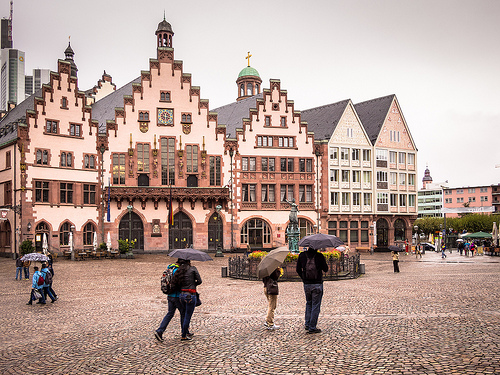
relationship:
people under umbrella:
[147, 248, 335, 350] [168, 247, 208, 265]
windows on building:
[67, 191, 73, 204] [209, 76, 325, 247]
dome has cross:
[236, 65, 260, 78] [243, 50, 253, 64]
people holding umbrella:
[294, 247, 328, 332] [254, 242, 291, 282]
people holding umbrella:
[294, 247, 328, 332] [166, 242, 212, 264]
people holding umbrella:
[294, 247, 328, 332] [298, 232, 337, 253]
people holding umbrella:
[294, 247, 328, 332] [298, 231, 343, 245]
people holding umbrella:
[294, 247, 328, 332] [387, 239, 405, 252]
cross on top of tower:
[243, 48, 254, 66] [238, 64, 260, 97]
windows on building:
[249, 127, 309, 153] [5, 5, 430, 255]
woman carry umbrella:
[260, 266, 283, 331] [255, 244, 290, 280]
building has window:
[0, 6, 331, 263] [132, 107, 152, 125]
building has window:
[0, 6, 331, 263] [174, 107, 195, 127]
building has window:
[0, 6, 331, 263] [133, 166, 153, 186]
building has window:
[0, 6, 331, 263] [179, 167, 201, 187]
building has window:
[0, 6, 331, 263] [258, 156, 280, 176]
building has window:
[0, 8, 418, 261] [241, 183, 258, 204]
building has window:
[0, 8, 418, 261] [261, 184, 274, 201]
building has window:
[0, 8, 418, 261] [281, 185, 293, 202]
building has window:
[0, 8, 418, 261] [300, 185, 312, 204]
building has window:
[0, 8, 418, 261] [184, 143, 198, 173]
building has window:
[0, 6, 331, 263] [27, 174, 51, 204]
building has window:
[0, 6, 331, 263] [52, 178, 76, 205]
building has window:
[0, 6, 331, 263] [79, 178, 99, 205]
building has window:
[0, 6, 331, 263] [107, 147, 129, 184]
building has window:
[0, 6, 331, 263] [179, 140, 205, 187]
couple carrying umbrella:
[156, 258, 201, 343] [20, 250, 50, 262]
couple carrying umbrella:
[26, 262, 54, 304] [20, 250, 50, 262]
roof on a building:
[298, 97, 350, 148] [5, 5, 430, 255]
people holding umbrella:
[294, 247, 328, 332] [297, 232, 344, 249]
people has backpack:
[294, 247, 328, 332] [300, 255, 319, 275]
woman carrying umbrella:
[166, 246, 213, 347] [169, 246, 213, 268]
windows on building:
[67, 191, 73, 204] [2, 1, 499, 256]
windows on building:
[279, 135, 296, 148] [2, 1, 499, 256]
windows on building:
[209, 155, 223, 185] [2, 1, 499, 256]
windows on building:
[352, 191, 359, 205] [2, 1, 499, 256]